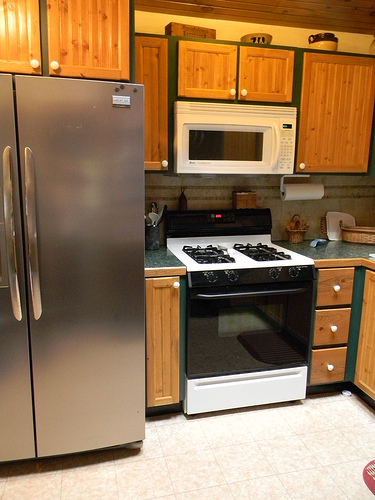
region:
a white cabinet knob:
[238, 86, 249, 98]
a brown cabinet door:
[238, 43, 295, 105]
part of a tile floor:
[0, 393, 374, 498]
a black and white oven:
[155, 201, 321, 417]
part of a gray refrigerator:
[0, 71, 150, 466]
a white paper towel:
[279, 181, 326, 201]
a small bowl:
[308, 32, 341, 49]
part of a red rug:
[361, 459, 373, 495]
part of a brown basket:
[338, 223, 373, 245]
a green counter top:
[144, 242, 184, 268]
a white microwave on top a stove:
[168, 92, 312, 295]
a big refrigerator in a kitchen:
[1, 65, 156, 468]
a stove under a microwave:
[168, 88, 315, 422]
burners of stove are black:
[180, 235, 300, 273]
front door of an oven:
[187, 271, 314, 377]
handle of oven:
[189, 280, 307, 304]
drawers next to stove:
[309, 265, 356, 395]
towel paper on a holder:
[273, 172, 328, 206]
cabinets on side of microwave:
[143, 41, 372, 181]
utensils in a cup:
[144, 197, 170, 253]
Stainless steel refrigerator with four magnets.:
[0, 71, 145, 459]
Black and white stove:
[164, 208, 314, 414]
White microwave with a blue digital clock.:
[174, 101, 295, 174]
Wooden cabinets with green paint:
[167, 37, 302, 106]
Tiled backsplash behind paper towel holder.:
[145, 171, 374, 240]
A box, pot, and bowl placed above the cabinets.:
[135, 9, 374, 172]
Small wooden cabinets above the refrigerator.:
[0, 0, 145, 462]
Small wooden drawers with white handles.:
[308, 266, 356, 384]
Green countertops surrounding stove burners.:
[145, 239, 374, 267]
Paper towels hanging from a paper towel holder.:
[281, 174, 323, 198]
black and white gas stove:
[163, 205, 317, 418]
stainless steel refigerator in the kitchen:
[2, 72, 148, 463]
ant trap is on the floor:
[340, 387, 353, 397]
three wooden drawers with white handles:
[309, 265, 354, 386]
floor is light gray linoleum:
[1, 393, 373, 495]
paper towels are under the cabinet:
[278, 174, 325, 201]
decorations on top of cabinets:
[163, 19, 339, 52]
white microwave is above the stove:
[171, 97, 296, 177]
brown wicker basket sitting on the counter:
[341, 222, 373, 244]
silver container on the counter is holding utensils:
[143, 200, 168, 250]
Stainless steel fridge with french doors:
[0, 68, 145, 463]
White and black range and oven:
[161, 205, 316, 417]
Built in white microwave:
[171, 97, 299, 177]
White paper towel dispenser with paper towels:
[276, 173, 326, 203]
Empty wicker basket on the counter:
[336, 217, 374, 248]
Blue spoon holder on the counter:
[306, 233, 329, 250]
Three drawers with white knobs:
[306, 259, 356, 388]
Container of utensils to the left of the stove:
[144, 195, 167, 255]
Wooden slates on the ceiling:
[135, 0, 373, 36]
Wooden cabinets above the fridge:
[0, 0, 131, 83]